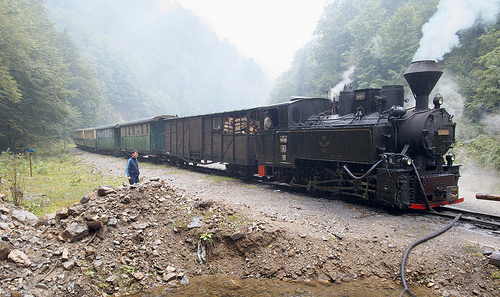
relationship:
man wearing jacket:
[126, 147, 141, 185] [126, 157, 139, 173]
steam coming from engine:
[412, 0, 499, 60] [259, 60, 464, 214]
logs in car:
[222, 114, 261, 137] [164, 96, 337, 188]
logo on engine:
[317, 134, 331, 156] [259, 60, 464, 214]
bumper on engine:
[411, 197, 463, 210] [259, 60, 464, 214]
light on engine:
[437, 97, 443, 106] [259, 60, 464, 214]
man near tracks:
[126, 147, 141, 185] [77, 143, 499, 233]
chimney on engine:
[404, 59, 443, 109] [259, 60, 464, 214]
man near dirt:
[126, 147, 141, 185] [0, 178, 354, 296]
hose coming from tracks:
[402, 212, 462, 294] [77, 143, 499, 233]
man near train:
[126, 147, 141, 185] [72, 61, 463, 216]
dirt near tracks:
[0, 178, 354, 296] [77, 143, 499, 233]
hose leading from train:
[402, 212, 462, 294] [72, 61, 463, 216]